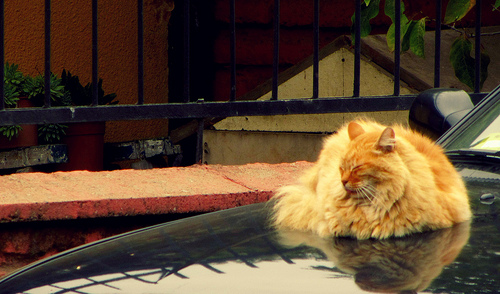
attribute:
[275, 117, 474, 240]
cat — sleeping, asleep, orange, tan, furry, sitting, fluffy, reclined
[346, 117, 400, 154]
ears — perked up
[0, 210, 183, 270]
wall — brick, red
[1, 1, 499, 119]
railing — metal, barred, iron, black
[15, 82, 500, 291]
car — parked, black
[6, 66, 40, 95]
leaves — green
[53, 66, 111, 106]
plant — spiky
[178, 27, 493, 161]
shed — small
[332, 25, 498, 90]
roof — brown, small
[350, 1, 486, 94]
leaves — large, hanging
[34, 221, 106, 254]
brick — red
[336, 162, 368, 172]
eyes — closed